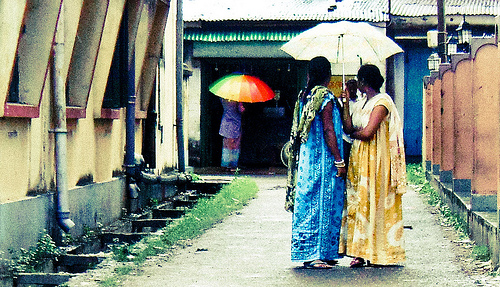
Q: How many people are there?
A: Four.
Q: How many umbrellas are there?
A: Two.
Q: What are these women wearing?
A: Sarongs.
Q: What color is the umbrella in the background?
A: Multi colored.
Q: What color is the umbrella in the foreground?
A: White.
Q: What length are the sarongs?
A: Ankle length.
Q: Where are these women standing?
A: In the walkway.